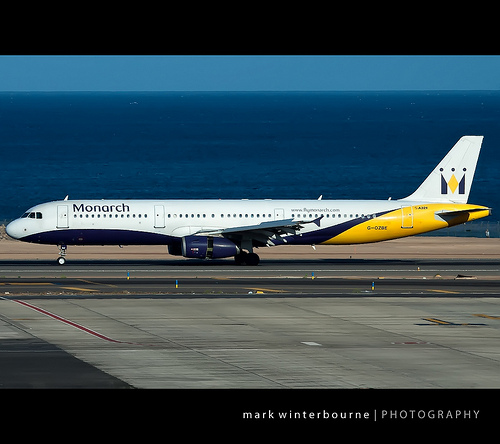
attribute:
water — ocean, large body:
[3, 90, 499, 239]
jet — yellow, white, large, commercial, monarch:
[3, 127, 493, 270]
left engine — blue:
[179, 234, 255, 264]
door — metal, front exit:
[54, 202, 72, 231]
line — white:
[3, 266, 493, 275]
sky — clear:
[1, 54, 496, 95]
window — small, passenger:
[143, 211, 148, 220]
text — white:
[239, 403, 485, 423]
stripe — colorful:
[10, 295, 120, 344]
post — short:
[365, 273, 377, 294]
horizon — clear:
[2, 84, 497, 98]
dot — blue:
[436, 163, 445, 176]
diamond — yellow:
[446, 168, 460, 197]